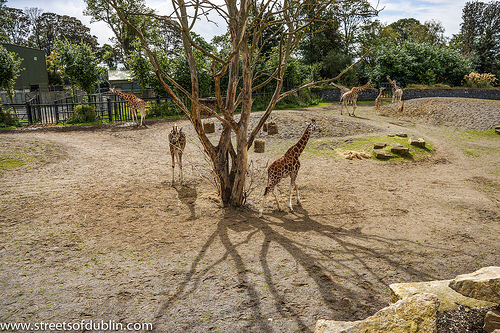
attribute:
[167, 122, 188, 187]
giraffe — looking forward, bending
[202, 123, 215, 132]
food — hanging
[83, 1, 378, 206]
tree — centered, central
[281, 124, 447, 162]
grass — green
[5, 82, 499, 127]
fence — metal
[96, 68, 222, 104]
building — green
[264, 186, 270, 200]
tip of tail — black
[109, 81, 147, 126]
giraffe — alone, spotted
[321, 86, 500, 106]
wall — stone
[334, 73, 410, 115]
giraffes — farthest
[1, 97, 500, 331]
ground — dirt, soil